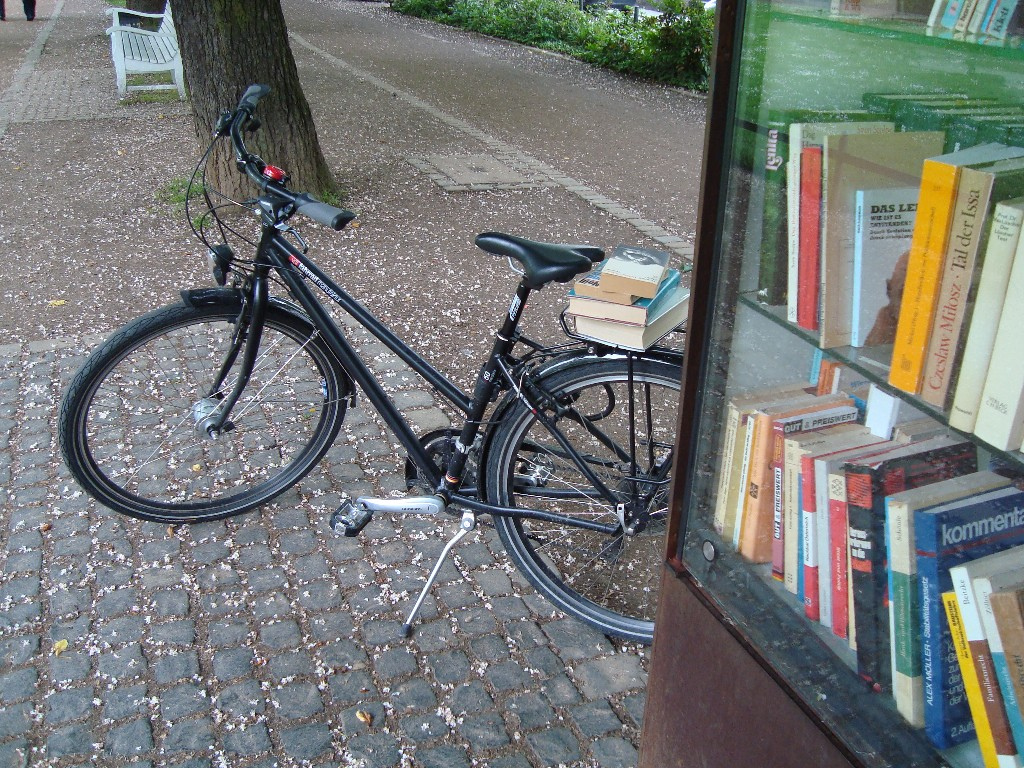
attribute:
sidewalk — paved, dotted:
[0, 4, 713, 765]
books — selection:
[712, 4, 1022, 765]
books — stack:
[571, 257, 690, 350]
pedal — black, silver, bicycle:
[327, 492, 444, 536]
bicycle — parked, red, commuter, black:
[59, 86, 690, 640]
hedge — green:
[384, 0, 717, 94]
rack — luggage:
[558, 305, 692, 528]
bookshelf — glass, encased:
[639, 0, 1022, 765]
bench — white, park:
[101, 4, 184, 97]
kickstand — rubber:
[401, 512, 479, 638]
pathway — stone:
[0, 0, 698, 763]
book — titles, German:
[712, 386, 1019, 765]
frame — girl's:
[267, 227, 535, 498]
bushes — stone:
[384, 0, 720, 94]